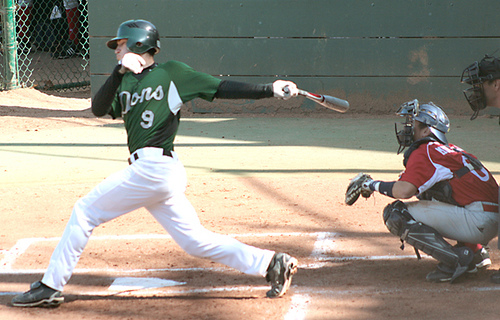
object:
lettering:
[153, 84, 165, 101]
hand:
[268, 79, 301, 101]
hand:
[117, 51, 145, 75]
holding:
[269, 77, 352, 116]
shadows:
[179, 105, 499, 165]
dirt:
[0, 87, 497, 320]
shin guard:
[382, 199, 459, 267]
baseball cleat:
[263, 250, 300, 299]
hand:
[353, 173, 380, 198]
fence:
[1, 0, 101, 95]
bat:
[281, 86, 350, 114]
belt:
[462, 198, 500, 214]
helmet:
[401, 102, 450, 145]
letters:
[118, 90, 130, 117]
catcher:
[339, 100, 500, 285]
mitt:
[341, 174, 375, 206]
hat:
[394, 100, 452, 143]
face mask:
[393, 98, 420, 148]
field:
[0, 86, 500, 320]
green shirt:
[87, 58, 225, 156]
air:
[0, 0, 395, 117]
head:
[110, 18, 161, 64]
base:
[104, 276, 189, 296]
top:
[90, 58, 271, 153]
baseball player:
[6, 18, 299, 308]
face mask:
[459, 62, 486, 112]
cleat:
[5, 279, 69, 309]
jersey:
[105, 61, 223, 152]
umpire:
[459, 51, 497, 122]